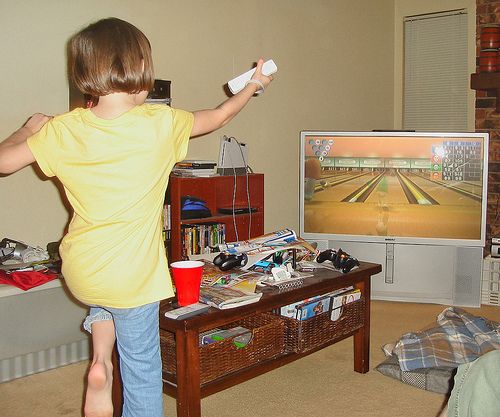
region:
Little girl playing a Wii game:
[7, 11, 285, 415]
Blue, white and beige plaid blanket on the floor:
[382, 297, 497, 388]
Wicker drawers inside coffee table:
[155, 285, 377, 384]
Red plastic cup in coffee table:
[160, 254, 220, 315]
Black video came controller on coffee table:
[314, 244, 361, 275]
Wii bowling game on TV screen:
[298, 129, 485, 246]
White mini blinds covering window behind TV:
[399, 32, 474, 139]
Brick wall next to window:
[477, 31, 497, 256]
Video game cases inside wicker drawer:
[273, 271, 372, 359]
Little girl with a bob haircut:
[60, 30, 172, 100]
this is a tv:
[305, 136, 346, 173]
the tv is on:
[343, 147, 405, 239]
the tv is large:
[309, 150, 386, 261]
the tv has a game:
[302, 133, 365, 218]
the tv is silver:
[295, 180, 392, 274]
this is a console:
[176, 142, 311, 188]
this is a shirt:
[142, 231, 166, 271]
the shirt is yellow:
[55, 177, 144, 232]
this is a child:
[75, 257, 140, 314]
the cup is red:
[166, 251, 271, 390]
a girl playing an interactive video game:
[1, 15, 277, 415]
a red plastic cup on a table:
[173, 262, 203, 305]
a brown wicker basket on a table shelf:
[161, 308, 284, 383]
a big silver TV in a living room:
[301, 132, 486, 310]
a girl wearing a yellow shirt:
[29, 103, 191, 303]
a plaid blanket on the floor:
[378, 304, 498, 392]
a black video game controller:
[317, 246, 359, 273]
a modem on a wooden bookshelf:
[217, 138, 249, 175]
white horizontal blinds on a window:
[403, 12, 468, 130]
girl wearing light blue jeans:
[82, 300, 162, 415]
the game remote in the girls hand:
[226, 49, 276, 107]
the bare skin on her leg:
[81, 322, 116, 361]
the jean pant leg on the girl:
[117, 308, 166, 415]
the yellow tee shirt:
[31, 107, 181, 301]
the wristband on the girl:
[241, 79, 268, 98]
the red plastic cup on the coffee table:
[170, 254, 208, 303]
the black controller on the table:
[314, 245, 361, 275]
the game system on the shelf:
[216, 136, 253, 174]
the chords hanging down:
[226, 140, 258, 240]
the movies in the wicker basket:
[282, 282, 362, 348]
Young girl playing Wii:
[0, 17, 279, 415]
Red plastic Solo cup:
[170, 259, 204, 306]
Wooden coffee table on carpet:
[105, 241, 382, 416]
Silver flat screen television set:
[298, 131, 488, 307]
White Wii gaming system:
[215, 136, 248, 173]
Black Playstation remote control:
[315, 246, 357, 271]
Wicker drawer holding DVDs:
[264, 281, 365, 352]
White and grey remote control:
[163, 301, 209, 321]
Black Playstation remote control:
[212, 249, 249, 271]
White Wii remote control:
[225, 58, 278, 95]